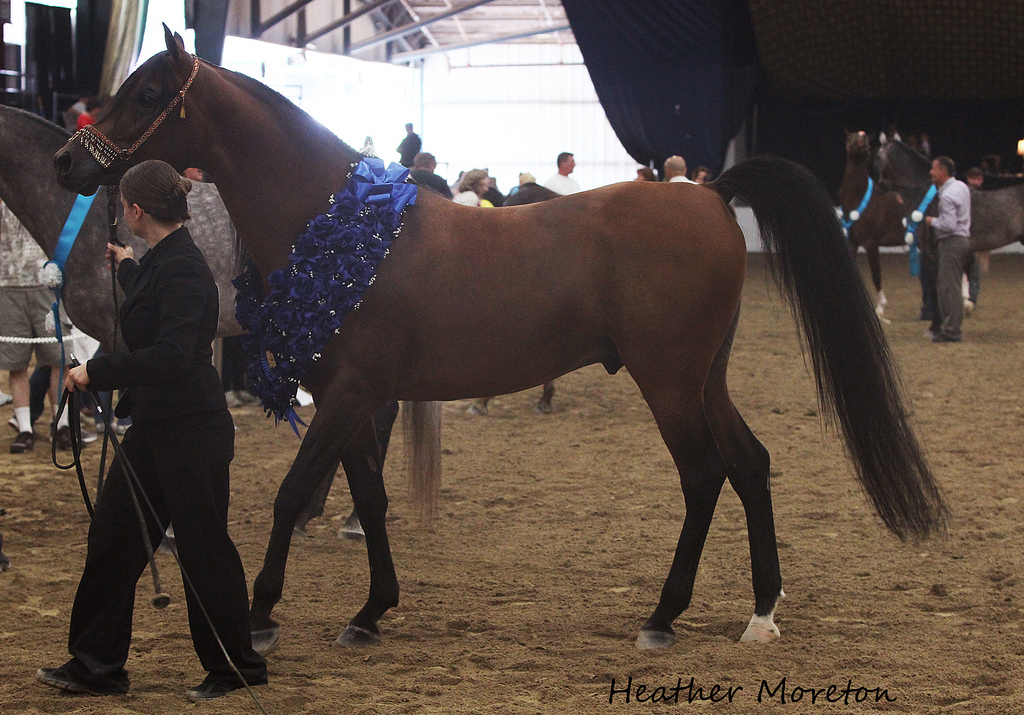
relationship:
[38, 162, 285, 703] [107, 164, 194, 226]
person has hair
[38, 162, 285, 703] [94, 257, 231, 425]
person wearing jacket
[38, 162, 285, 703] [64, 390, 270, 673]
person wearing pants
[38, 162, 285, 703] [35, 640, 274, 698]
person wearing shoes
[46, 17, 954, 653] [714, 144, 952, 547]
horse has tail